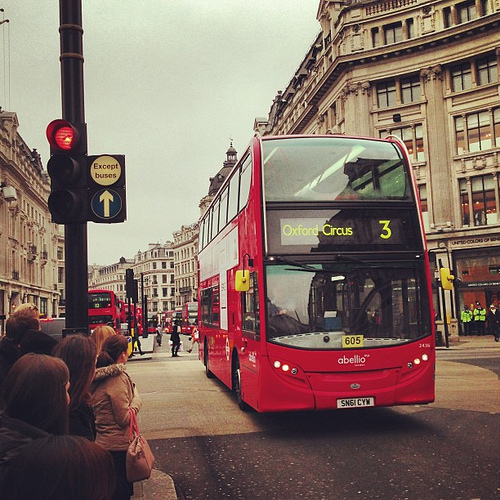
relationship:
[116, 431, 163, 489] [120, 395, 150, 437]
purse has handles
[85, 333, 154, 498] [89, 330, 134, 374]
person has head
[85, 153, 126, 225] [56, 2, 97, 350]
sign on pole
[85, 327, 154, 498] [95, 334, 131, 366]
person has hair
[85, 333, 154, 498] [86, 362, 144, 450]
person wearing jacket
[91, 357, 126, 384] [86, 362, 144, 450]
fur on jacket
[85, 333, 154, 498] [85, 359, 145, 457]
person wearing coat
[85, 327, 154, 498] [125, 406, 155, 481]
person holding purse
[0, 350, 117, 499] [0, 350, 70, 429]
person has hair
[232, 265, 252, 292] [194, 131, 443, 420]
mirror on side of bus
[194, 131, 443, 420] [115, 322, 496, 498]
bus in road